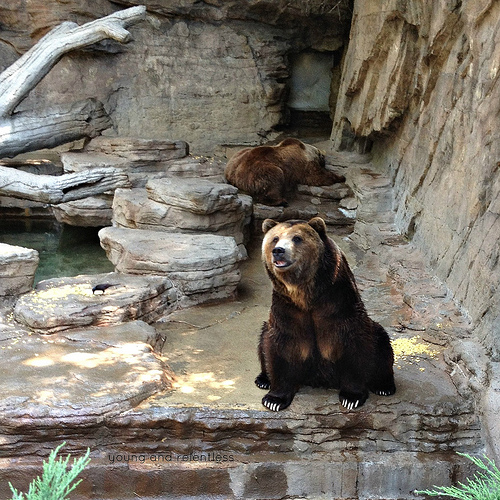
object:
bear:
[245, 217, 398, 411]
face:
[267, 229, 314, 281]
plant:
[8, 440, 92, 499]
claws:
[341, 397, 363, 411]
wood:
[0, 4, 149, 204]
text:
[106, 452, 236, 463]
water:
[0, 217, 118, 285]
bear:
[224, 137, 346, 205]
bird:
[91, 282, 121, 294]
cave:
[291, 46, 336, 134]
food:
[389, 335, 439, 362]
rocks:
[0, 138, 499, 499]